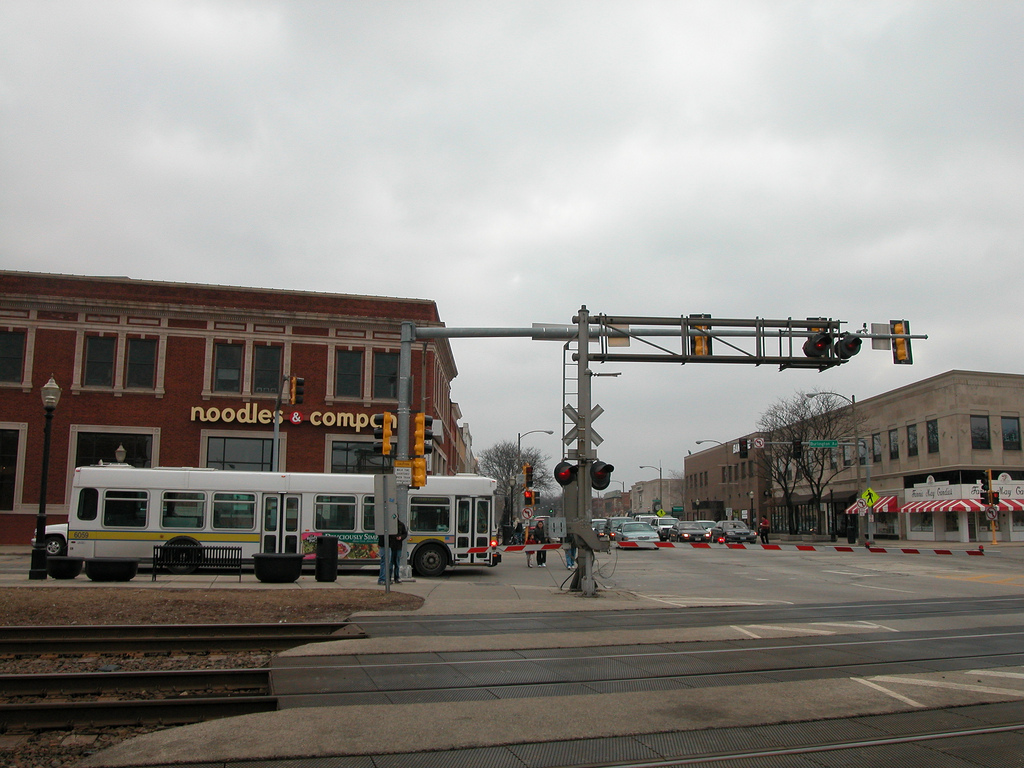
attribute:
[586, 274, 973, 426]
signs — warning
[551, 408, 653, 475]
sign — crossing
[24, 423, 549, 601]
bus — painted, white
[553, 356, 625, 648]
pole — metal, light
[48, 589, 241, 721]
tracks — metal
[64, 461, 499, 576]
bus — long, white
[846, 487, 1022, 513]
awning — red, white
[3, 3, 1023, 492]
sky — gray, cloudy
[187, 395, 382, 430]
sign — noodles & company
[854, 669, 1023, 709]
lines — white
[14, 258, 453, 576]
building — large, red, brick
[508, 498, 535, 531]
sign — do, not, turn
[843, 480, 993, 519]
awning — red, white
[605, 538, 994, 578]
crossing — railroad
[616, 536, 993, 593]
crossing — railroad